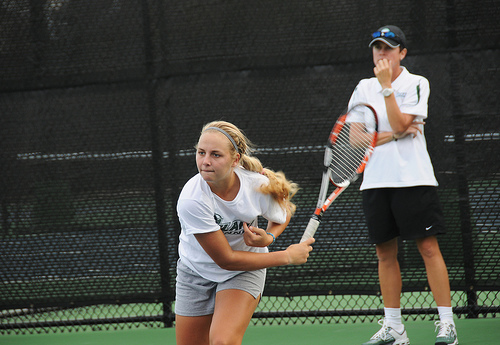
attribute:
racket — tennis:
[284, 95, 380, 268]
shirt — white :
[174, 166, 295, 278]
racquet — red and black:
[298, 104, 381, 262]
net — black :
[6, 3, 498, 327]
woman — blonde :
[171, 121, 297, 341]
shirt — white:
[174, 164, 288, 284]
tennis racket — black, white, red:
[297, 101, 381, 242]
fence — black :
[2, 2, 483, 334]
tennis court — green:
[0, 314, 484, 342]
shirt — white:
[344, 64, 441, 192]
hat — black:
[365, 22, 408, 49]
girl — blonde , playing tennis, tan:
[171, 116, 314, 343]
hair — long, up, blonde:
[198, 118, 300, 219]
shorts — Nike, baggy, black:
[360, 184, 449, 245]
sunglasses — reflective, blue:
[370, 30, 404, 46]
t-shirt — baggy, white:
[173, 163, 288, 283]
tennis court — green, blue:
[1, 177, 484, 343]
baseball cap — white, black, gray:
[366, 24, 407, 50]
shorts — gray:
[170, 256, 267, 322]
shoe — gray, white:
[357, 315, 411, 343]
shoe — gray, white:
[431, 319, 462, 343]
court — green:
[69, 287, 393, 343]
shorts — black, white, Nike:
[349, 182, 474, 272]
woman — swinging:
[176, 115, 302, 342]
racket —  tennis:
[308, 104, 396, 232]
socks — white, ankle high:
[381, 306, 453, 325]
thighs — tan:
[174, 288, 257, 343]